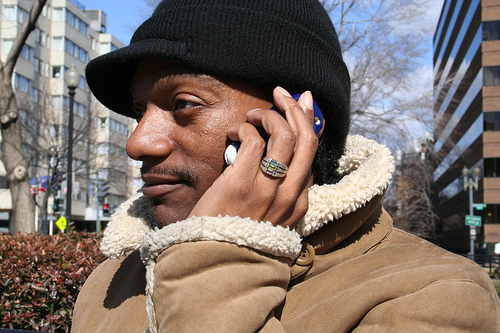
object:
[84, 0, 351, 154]
cap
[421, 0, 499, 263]
building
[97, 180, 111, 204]
lights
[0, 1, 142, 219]
building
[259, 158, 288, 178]
ring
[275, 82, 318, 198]
finger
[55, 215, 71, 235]
sign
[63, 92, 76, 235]
pole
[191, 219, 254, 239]
wool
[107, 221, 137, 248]
wool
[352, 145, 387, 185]
wool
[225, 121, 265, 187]
finger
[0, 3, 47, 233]
tree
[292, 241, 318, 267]
button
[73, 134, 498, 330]
coat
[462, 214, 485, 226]
sign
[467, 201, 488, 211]
sign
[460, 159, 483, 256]
pole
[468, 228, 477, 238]
sign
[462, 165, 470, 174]
light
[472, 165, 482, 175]
light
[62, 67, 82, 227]
streetlamp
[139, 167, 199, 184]
mustache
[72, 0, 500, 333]
man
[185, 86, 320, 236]
hand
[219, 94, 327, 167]
cell phone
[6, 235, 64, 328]
bush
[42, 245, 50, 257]
leaves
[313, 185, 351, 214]
wool